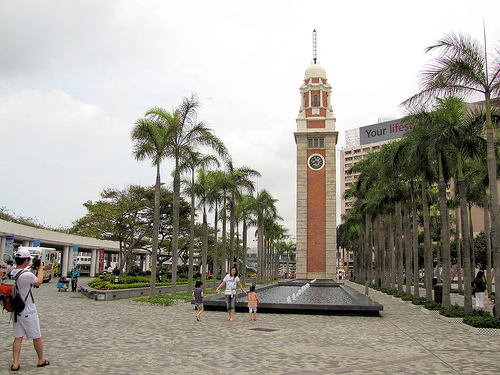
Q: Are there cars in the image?
A: No, there are no cars.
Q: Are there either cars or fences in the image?
A: No, there are no cars or fences.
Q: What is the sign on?
A: The sign is on the building.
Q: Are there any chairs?
A: No, there are no chairs.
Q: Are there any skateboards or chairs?
A: No, there are no chairs or skateboards.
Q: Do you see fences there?
A: No, there are no fences.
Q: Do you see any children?
A: Yes, there are children.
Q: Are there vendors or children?
A: Yes, there are children.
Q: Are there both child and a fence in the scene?
A: No, there are children but no fences.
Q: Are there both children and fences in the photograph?
A: No, there are children but no fences.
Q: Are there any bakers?
A: No, there are no bakers.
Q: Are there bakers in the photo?
A: No, there are no bakers.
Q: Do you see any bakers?
A: No, there are no bakers.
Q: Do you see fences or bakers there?
A: No, there are no bakers or fences.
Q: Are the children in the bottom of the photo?
A: Yes, the children are in the bottom of the image.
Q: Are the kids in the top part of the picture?
A: No, the kids are in the bottom of the image.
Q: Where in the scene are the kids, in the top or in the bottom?
A: The kids are in the bottom of the image.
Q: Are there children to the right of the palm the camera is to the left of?
A: Yes, there are children to the right of the palm tree.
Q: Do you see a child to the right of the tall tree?
A: Yes, there are children to the right of the palm tree.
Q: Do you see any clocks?
A: Yes, there is a clock.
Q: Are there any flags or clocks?
A: Yes, there is a clock.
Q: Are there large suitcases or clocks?
A: Yes, there is a large clock.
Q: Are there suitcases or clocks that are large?
A: Yes, the clock is large.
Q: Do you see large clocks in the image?
A: Yes, there is a large clock.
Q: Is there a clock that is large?
A: Yes, there is a clock that is large.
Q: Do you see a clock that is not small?
A: Yes, there is a large clock.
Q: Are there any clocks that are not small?
A: Yes, there is a large clock.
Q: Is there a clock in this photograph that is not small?
A: Yes, there is a large clock.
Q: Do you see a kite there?
A: No, there are no kites.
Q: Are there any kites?
A: No, there are no kites.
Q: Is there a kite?
A: No, there are no kites.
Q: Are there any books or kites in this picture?
A: No, there are no kites or books.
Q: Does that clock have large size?
A: Yes, the clock is large.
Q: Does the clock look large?
A: Yes, the clock is large.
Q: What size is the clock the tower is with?
A: The clock is large.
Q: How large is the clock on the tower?
A: The clock is large.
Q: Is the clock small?
A: No, the clock is large.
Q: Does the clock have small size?
A: No, the clock is large.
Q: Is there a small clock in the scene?
A: No, there is a clock but it is large.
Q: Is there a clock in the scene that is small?
A: No, there is a clock but it is large.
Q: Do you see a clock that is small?
A: No, there is a clock but it is large.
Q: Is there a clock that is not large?
A: No, there is a clock but it is large.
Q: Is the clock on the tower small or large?
A: The clock is large.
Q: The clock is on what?
A: The clock is on the tower.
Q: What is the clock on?
A: The clock is on the tower.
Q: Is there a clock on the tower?
A: Yes, there is a clock on the tower.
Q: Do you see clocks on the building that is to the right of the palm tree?
A: Yes, there is a clock on the tower.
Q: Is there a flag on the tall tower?
A: No, there is a clock on the tower.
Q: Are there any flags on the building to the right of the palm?
A: No, there is a clock on the tower.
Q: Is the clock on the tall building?
A: Yes, the clock is on the tower.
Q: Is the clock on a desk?
A: No, the clock is on the tower.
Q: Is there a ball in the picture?
A: No, there are no balls.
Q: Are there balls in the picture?
A: No, there are no balls.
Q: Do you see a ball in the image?
A: No, there are no balls.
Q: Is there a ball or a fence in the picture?
A: No, there are no balls or fences.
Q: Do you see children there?
A: Yes, there is a child.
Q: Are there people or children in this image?
A: Yes, there is a child.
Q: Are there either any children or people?
A: Yes, there is a child.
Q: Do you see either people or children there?
A: Yes, there is a child.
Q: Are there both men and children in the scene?
A: Yes, there are both a child and a man.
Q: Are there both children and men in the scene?
A: Yes, there are both a child and a man.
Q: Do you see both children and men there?
A: Yes, there are both a child and a man.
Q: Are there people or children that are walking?
A: Yes, the child is walking.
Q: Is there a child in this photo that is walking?
A: Yes, there is a child that is walking.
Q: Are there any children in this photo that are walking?
A: Yes, there is a child that is walking.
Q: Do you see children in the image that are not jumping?
A: Yes, there is a child that is walking .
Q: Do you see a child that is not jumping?
A: Yes, there is a child that is walking .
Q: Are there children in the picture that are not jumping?
A: Yes, there is a child that is walking.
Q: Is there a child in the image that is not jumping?
A: Yes, there is a child that is walking.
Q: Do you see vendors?
A: No, there are no vendors.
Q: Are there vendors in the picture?
A: No, there are no vendors.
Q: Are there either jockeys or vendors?
A: No, there are no vendors or jockeys.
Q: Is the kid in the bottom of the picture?
A: Yes, the kid is in the bottom of the image.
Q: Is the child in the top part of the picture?
A: No, the child is in the bottom of the image.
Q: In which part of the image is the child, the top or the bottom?
A: The child is in the bottom of the image.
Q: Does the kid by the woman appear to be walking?
A: Yes, the kid is walking.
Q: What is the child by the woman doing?
A: The kid is walking.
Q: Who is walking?
A: The child is walking.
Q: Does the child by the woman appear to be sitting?
A: No, the child is walking.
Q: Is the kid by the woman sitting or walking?
A: The child is walking.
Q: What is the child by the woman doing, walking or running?
A: The child is walking.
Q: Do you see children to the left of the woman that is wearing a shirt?
A: Yes, there is a child to the left of the woman.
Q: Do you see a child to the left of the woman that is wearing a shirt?
A: Yes, there is a child to the left of the woman.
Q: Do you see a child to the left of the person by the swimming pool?
A: Yes, there is a child to the left of the woman.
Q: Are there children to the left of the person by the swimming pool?
A: Yes, there is a child to the left of the woman.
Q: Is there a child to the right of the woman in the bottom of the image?
A: No, the child is to the left of the woman.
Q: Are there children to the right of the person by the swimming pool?
A: No, the child is to the left of the woman.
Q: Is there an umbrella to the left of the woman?
A: No, there is a child to the left of the woman.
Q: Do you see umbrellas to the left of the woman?
A: No, there is a child to the left of the woman.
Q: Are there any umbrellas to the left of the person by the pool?
A: No, there is a child to the left of the woman.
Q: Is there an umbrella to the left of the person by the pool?
A: No, there is a child to the left of the woman.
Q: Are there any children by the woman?
A: Yes, there is a child by the woman.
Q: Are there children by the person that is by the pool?
A: Yes, there is a child by the woman.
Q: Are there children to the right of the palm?
A: Yes, there is a child to the right of the palm.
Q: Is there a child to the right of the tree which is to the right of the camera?
A: Yes, there is a child to the right of the palm.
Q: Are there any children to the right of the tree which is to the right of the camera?
A: Yes, there is a child to the right of the palm.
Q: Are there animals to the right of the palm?
A: No, there is a child to the right of the palm.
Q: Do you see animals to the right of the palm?
A: No, there is a child to the right of the palm.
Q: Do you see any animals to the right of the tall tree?
A: No, there is a child to the right of the palm.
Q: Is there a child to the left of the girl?
A: Yes, there is a child to the left of the girl.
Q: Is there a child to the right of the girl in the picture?
A: No, the child is to the left of the girl.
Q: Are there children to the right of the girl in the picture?
A: No, the child is to the left of the girl.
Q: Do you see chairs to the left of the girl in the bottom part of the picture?
A: No, there is a child to the left of the girl.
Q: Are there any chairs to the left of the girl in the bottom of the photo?
A: No, there is a child to the left of the girl.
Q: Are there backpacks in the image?
A: Yes, there is a backpack.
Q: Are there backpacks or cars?
A: Yes, there is a backpack.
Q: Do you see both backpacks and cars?
A: No, there is a backpack but no cars.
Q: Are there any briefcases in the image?
A: No, there are no briefcases.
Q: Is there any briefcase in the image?
A: No, there are no briefcases.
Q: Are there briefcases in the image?
A: No, there are no briefcases.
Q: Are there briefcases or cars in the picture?
A: No, there are no briefcases or cars.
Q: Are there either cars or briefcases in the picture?
A: No, there are no briefcases or cars.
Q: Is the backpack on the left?
A: Yes, the backpack is on the left of the image.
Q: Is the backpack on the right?
A: No, the backpack is on the left of the image.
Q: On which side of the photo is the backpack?
A: The backpack is on the left of the image.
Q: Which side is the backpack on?
A: The backpack is on the left of the image.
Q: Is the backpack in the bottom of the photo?
A: Yes, the backpack is in the bottom of the image.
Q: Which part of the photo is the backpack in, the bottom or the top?
A: The backpack is in the bottom of the image.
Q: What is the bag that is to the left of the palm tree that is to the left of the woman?
A: The bag is a backpack.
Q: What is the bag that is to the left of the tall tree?
A: The bag is a backpack.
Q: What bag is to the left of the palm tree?
A: The bag is a backpack.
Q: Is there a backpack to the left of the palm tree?
A: Yes, there is a backpack to the left of the palm tree.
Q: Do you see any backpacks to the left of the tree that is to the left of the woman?
A: Yes, there is a backpack to the left of the palm tree.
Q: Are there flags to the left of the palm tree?
A: No, there is a backpack to the left of the palm tree.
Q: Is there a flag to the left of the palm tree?
A: No, there is a backpack to the left of the palm tree.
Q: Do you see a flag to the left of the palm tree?
A: No, there is a backpack to the left of the palm tree.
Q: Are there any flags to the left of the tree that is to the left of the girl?
A: No, there is a backpack to the left of the palm tree.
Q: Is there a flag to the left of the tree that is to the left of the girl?
A: No, there is a backpack to the left of the palm tree.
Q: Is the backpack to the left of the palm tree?
A: Yes, the backpack is to the left of the palm tree.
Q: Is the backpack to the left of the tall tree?
A: Yes, the backpack is to the left of the palm tree.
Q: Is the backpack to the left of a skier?
A: No, the backpack is to the left of the palm tree.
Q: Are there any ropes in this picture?
A: No, there are no ropes.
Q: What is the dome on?
A: The dome is on the tower.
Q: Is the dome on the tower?
A: Yes, the dome is on the tower.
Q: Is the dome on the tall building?
A: Yes, the dome is on the tower.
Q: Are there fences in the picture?
A: No, there are no fences.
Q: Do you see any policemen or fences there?
A: No, there are no fences or policemen.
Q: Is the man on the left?
A: Yes, the man is on the left of the image.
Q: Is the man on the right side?
A: No, the man is on the left of the image.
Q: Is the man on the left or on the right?
A: The man is on the left of the image.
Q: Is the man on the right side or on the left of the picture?
A: The man is on the left of the image.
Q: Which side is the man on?
A: The man is on the left of the image.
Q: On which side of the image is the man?
A: The man is on the left of the image.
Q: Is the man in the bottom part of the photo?
A: Yes, the man is in the bottom of the image.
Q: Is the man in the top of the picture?
A: No, the man is in the bottom of the image.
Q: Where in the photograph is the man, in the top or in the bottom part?
A: The man is in the bottom of the image.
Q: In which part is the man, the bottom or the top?
A: The man is in the bottom of the image.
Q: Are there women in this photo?
A: Yes, there is a woman.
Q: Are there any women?
A: Yes, there is a woman.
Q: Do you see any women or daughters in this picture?
A: Yes, there is a woman.